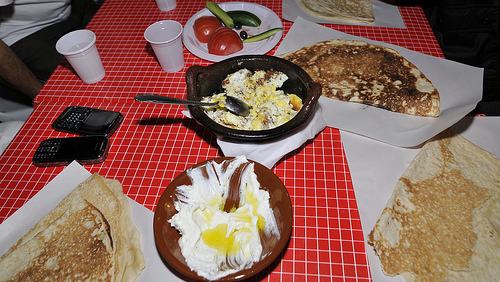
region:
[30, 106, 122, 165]
Two cell phones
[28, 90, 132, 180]
Cellphones resting on top of the table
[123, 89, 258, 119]
A silver spoon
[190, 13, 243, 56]
Red tomatoes sliced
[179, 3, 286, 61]
A round white plate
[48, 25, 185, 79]
White cups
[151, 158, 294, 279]
A brown bowl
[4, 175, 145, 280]
Flat cooked bread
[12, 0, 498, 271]
A table with food on it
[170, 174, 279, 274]
cream and butter in a bowl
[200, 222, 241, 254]
a pool of melted butter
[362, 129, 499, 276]
a folded brown tortilla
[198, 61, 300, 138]
fried eggs in a skillet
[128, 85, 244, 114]
a long metal spoon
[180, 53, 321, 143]
a black cast iron skillet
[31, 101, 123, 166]
two cell phones on a table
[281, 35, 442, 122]
dark brown folded bread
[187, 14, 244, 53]
tomato halves on a plate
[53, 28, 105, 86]
white plastic cup of water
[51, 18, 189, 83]
two white plastic cups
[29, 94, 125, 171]
two black phones laying next to each other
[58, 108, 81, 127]
buttons o the phone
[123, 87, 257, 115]
spoon laying in the food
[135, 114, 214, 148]
shadow on the table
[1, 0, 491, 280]
two tables pushed together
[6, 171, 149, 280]
very large pancake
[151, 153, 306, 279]
whipped cream in a bowl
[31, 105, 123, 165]
two black cell phones on the table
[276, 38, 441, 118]
crepe folded in half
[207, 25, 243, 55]
red tomato is sliced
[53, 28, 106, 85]
white plastic cup with a clear beverage in it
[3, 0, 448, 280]
table with red and white checkered tablecloth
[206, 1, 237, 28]
green slice of a pickle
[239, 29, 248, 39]
oval black olive on a plate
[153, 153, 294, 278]
round brown plate with a dipping sauce on it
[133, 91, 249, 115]
silver spoon upside down in a dish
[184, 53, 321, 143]
black cast iron skillet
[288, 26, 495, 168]
Bread on wax paper.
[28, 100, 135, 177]
Two phones on a table.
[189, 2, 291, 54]
Vegetables on a plate.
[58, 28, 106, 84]
Water in a plastic cup.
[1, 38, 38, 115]
Black arm in the background.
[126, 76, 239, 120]
Spoon in a dish.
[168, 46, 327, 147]
Cast iron skillet in the middle.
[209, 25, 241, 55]
Sliced tomato on a plate.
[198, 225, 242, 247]
Yellow of an egg in a bowl.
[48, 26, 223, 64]
Plastic cups on top of the table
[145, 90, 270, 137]
Metal spoon in the dish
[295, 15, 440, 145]
Folded pancake on a piece of deli paper